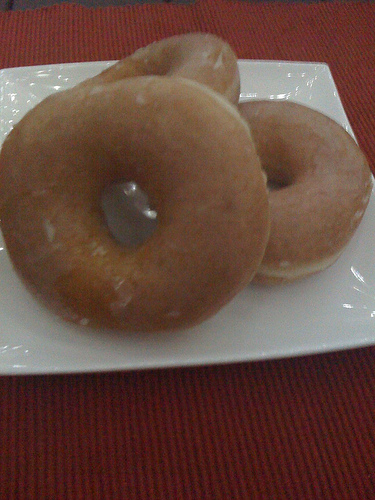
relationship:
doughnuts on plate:
[9, 44, 374, 336] [9, 55, 374, 393]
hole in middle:
[108, 177, 150, 244] [45, 113, 216, 269]